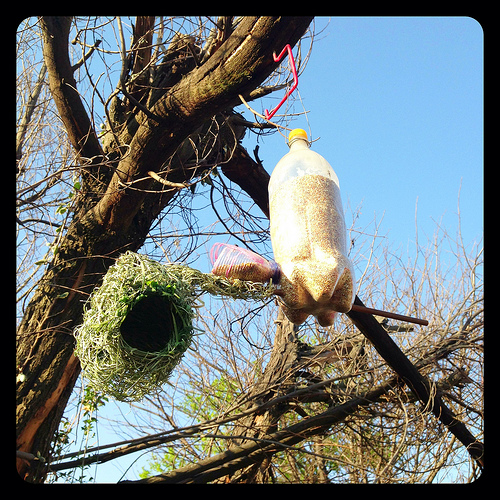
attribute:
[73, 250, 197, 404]
nest — grass, empty, green, large, yellow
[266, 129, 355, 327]
bottle — plastic, full, large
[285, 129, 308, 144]
cap — yellow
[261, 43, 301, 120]
object — red, metallic, pink, metal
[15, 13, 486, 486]
tree — brown, bare, large, big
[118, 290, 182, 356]
hole — dark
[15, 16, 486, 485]
sky — blue, clear, bright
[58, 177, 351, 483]
leaves — green